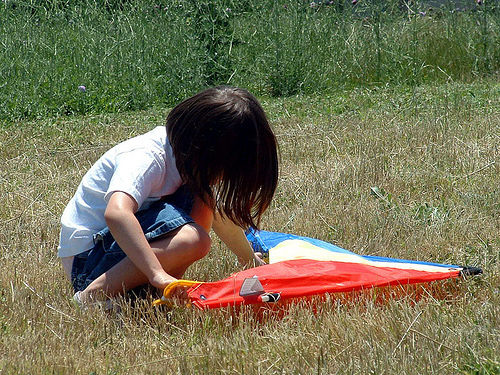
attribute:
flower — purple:
[73, 80, 89, 94]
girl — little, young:
[62, 82, 278, 305]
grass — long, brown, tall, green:
[0, 79, 498, 372]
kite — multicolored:
[167, 223, 477, 310]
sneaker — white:
[64, 285, 122, 317]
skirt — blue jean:
[69, 181, 221, 293]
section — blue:
[242, 221, 462, 272]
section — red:
[187, 256, 464, 308]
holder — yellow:
[152, 269, 213, 307]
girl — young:
[62, 89, 285, 294]